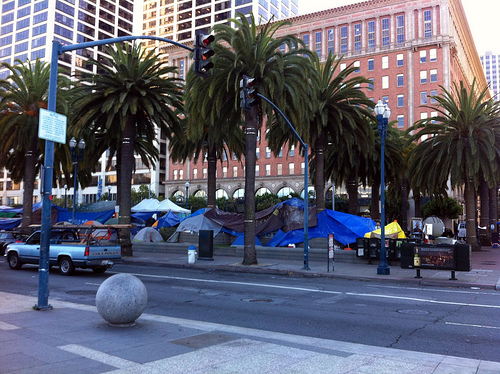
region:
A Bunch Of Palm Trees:
[1, 14, 498, 265]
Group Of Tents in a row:
[48, 195, 410, 251]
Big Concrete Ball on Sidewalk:
[90, 269, 148, 328]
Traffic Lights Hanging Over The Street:
[48, 29, 340, 304]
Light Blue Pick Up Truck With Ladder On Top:
[2, 218, 133, 280]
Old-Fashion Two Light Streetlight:
[373, 98, 393, 273]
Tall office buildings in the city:
[1, 0, 497, 237]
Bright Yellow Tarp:
[366, 218, 406, 248]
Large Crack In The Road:
[380, 288, 489, 349]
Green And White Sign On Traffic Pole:
[35, 106, 67, 149]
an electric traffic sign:
[191, 32, 216, 77]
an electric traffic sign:
[238, 74, 255, 108]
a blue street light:
[373, 97, 391, 275]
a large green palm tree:
[182, 17, 314, 264]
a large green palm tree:
[66, 40, 178, 261]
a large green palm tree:
[174, 107, 241, 207]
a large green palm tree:
[0, 57, 85, 229]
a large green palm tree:
[407, 76, 497, 250]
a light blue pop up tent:
[132, 225, 164, 244]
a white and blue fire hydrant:
[187, 244, 196, 264]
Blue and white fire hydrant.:
[181, 244, 199, 266]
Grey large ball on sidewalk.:
[91, 256, 149, 326]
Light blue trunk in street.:
[2, 227, 123, 273]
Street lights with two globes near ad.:
[372, 87, 392, 272]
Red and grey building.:
[165, 0, 480, 205]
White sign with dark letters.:
[35, 105, 70, 145]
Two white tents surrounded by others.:
[130, 195, 187, 210]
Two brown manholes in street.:
[242, 292, 427, 318]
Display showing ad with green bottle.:
[397, 235, 472, 278]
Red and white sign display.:
[326, 224, 336, 259]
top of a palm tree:
[215, 20, 308, 120]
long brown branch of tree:
[231, 140, 276, 268]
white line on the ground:
[262, 269, 330, 311]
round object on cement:
[84, 267, 160, 329]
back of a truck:
[77, 235, 126, 267]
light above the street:
[223, 65, 283, 116]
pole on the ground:
[291, 135, 325, 284]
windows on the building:
[410, 59, 445, 91]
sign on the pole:
[28, 100, 78, 152]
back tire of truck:
[55, 250, 82, 277]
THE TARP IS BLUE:
[279, 197, 385, 257]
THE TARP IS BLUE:
[273, 158, 418, 303]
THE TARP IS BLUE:
[246, 180, 378, 276]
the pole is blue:
[23, 23, 85, 340]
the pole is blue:
[285, 122, 316, 293]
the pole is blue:
[346, 110, 404, 309]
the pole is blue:
[50, 20, 93, 366]